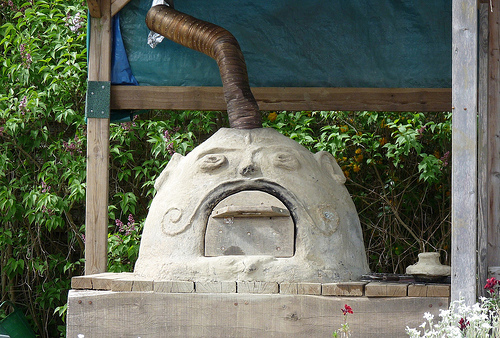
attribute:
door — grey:
[203, 188, 298, 257]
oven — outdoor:
[95, 24, 405, 307]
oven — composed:
[132, 125, 371, 281]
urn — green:
[0, 307, 40, 336]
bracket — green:
[83, 78, 111, 120]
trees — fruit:
[263, 110, 450, 272]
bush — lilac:
[6, 48, 143, 335]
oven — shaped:
[201, 187, 296, 257]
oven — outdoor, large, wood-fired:
[132, 119, 376, 290]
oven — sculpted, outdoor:
[126, 107, 455, 295]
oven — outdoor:
[204, 163, 316, 275]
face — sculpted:
[156, 139, 345, 262]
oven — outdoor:
[129, 101, 371, 281]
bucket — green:
[10, 311, 50, 333]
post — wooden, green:
[81, 14, 108, 271]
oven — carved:
[157, 103, 373, 285]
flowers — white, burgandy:
[404, 278, 499, 335]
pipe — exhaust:
[134, 3, 274, 130]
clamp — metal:
[73, 70, 135, 125]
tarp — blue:
[116, 20, 462, 102]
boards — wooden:
[67, 261, 425, 310]